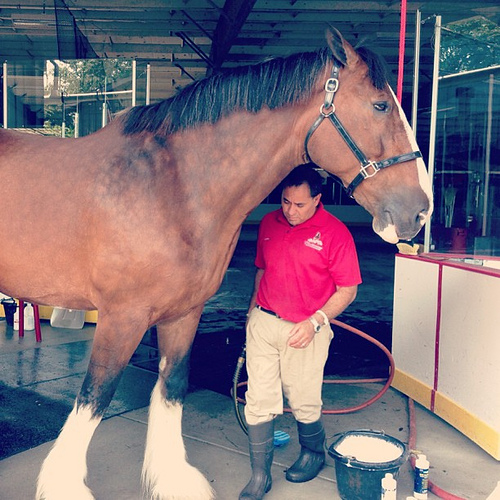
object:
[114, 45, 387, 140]
mane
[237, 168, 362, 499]
man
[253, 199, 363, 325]
shirt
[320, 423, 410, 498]
bucket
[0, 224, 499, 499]
floor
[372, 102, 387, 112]
horse eye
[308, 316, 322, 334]
watch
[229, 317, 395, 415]
hose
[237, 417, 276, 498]
rubber boots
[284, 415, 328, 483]
rubber boots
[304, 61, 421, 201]
harness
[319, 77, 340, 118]
buckle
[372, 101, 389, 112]
eye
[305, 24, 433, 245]
head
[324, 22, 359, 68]
horses ear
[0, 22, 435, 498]
horse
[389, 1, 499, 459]
partition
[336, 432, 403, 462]
soapy water